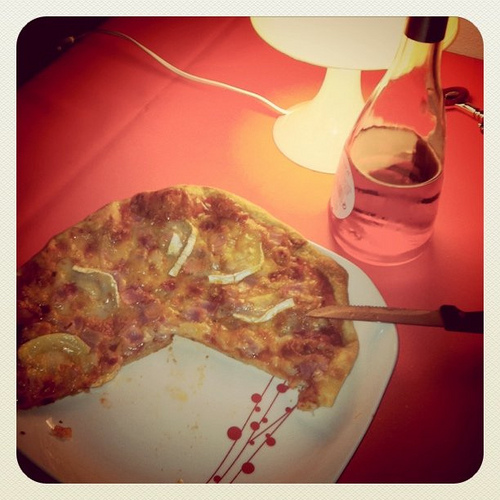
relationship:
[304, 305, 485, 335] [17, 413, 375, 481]
knife on plate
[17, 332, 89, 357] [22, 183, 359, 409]
topping on pizza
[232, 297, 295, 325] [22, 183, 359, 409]
topping on pizza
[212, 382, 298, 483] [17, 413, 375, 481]
flower on plate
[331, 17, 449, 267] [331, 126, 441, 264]
bottle of water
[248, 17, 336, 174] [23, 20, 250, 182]
lamp on table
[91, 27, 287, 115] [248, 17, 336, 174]
cord for lamp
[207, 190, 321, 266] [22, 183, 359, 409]
crust on pizza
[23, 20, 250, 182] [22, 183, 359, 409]
table with some pizza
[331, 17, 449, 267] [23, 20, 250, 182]
bottle on table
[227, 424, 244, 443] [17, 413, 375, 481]
dot on plate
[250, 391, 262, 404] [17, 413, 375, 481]
dot on plate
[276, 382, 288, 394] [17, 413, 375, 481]
dot on plate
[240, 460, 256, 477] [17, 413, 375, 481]
dot on plate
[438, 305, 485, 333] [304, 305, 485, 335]
handle of knife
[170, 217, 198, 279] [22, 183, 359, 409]
topping on pizza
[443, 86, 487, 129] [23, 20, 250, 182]
key on table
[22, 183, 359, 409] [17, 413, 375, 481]
pizza on plate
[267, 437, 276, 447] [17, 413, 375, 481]
dot on plate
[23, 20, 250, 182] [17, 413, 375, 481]
table on plate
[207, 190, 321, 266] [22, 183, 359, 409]
crust of pizza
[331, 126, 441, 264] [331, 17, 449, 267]
water in bottle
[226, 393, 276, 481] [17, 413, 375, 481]
dots on plate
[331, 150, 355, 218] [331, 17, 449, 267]
label on bottle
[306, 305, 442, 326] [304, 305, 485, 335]
blade of knife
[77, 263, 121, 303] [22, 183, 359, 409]
topping on pizza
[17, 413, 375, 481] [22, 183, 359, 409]
plate under pizza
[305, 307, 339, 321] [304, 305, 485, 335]
tip of knife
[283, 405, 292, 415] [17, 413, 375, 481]
dot on plate